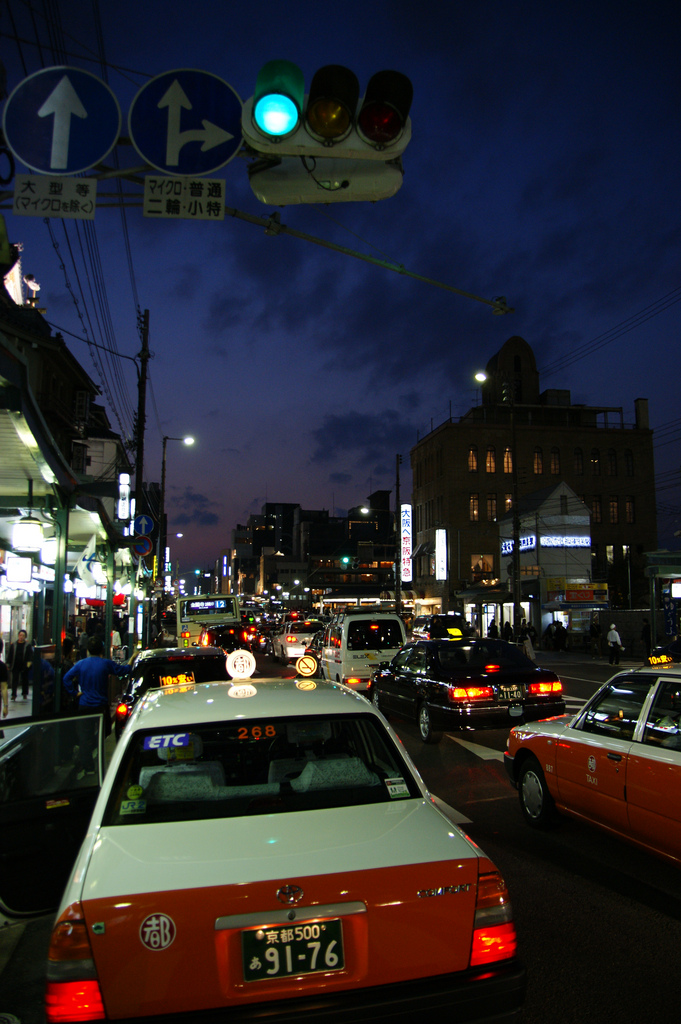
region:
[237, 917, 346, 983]
License plate on a car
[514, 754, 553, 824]
Tire on a car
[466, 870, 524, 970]
Tail light on a car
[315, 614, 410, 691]
White van in the street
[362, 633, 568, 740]
Black car parked in the street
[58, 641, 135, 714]
A man standing beside a car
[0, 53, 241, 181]
Blue and white traffic signs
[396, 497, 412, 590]
A sign on a building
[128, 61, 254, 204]
straight or turning sign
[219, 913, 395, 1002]
license plate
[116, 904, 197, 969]
sticker on the car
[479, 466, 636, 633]
tall white building with blue neon sign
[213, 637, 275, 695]
circle sign on top of taxi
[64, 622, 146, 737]
person in blue leaning on a car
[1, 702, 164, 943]
open door of the taxi cab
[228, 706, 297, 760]
number in the back window of taxi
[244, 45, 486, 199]
three light stop light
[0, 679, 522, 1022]
red and white taxi cab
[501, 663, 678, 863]
red and white taxi cab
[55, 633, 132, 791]
man wearing a blue sweater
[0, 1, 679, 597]
dark nighttime sky with sporadic clouds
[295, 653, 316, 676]
lit up no smoking sign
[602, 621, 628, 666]
man is a white shirt and hat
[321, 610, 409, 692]
white worker van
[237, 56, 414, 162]
white metal traffic light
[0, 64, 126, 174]
white and blue sign with an arrow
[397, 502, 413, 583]
tall thin sign with writing in an Asian language on it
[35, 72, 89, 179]
White arrow on blue traffic sign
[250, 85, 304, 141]
Traffic light is green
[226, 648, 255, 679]
Light atop taxi is illuminated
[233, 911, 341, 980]
Green and white license plate on the taxi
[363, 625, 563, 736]
Black car in front of a taxi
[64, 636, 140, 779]
Person wearing a blue shirt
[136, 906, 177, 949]
Red and white sticker on the taxi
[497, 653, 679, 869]
Taxi is red and white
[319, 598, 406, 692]
White van in front of the black car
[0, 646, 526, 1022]
Red and white taxi is parked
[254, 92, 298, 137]
the light is green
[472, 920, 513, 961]
the tail light is red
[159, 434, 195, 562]
the street light is tall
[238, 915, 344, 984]
the license plate is black and white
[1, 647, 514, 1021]
the car is red and white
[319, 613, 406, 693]
the small van is white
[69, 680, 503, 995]
A car on a street.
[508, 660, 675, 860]
A car on a street.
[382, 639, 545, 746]
A car on a street.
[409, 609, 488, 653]
A car on a street.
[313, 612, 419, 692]
A car on a street.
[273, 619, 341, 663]
A car on a street.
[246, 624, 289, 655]
A car on a street.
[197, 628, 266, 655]
A car on a street.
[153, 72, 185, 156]
White arrow on blue traffic sign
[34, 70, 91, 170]
White arrow on blue traffic sign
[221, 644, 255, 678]
Light lit on taxi roof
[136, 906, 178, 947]
Red and white sticker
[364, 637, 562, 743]
Black sedan in front of the taxi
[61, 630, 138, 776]
Person wearing a blue shirt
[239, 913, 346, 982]
Green and white license plate on the taxi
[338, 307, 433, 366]
clouds in the sky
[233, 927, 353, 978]
a license plate